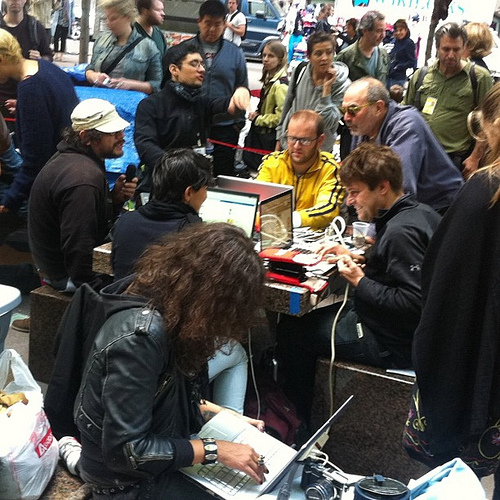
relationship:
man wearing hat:
[30, 93, 153, 316] [68, 91, 133, 134]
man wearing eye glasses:
[131, 41, 212, 198] [185, 58, 205, 68]